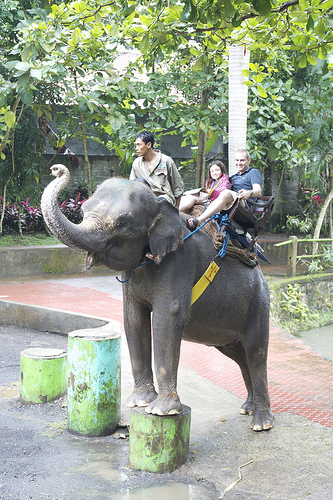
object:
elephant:
[40, 164, 278, 434]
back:
[169, 206, 275, 294]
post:
[18, 347, 65, 407]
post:
[128, 403, 191, 472]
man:
[129, 126, 183, 211]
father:
[174, 147, 264, 230]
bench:
[219, 194, 275, 252]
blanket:
[189, 202, 259, 267]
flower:
[311, 195, 322, 206]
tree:
[60, 0, 329, 176]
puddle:
[128, 484, 214, 500]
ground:
[25, 407, 333, 499]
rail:
[274, 232, 290, 254]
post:
[67, 327, 125, 437]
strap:
[186, 258, 219, 304]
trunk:
[39, 163, 88, 249]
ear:
[148, 196, 184, 267]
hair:
[134, 130, 154, 147]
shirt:
[128, 152, 184, 203]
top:
[205, 180, 235, 196]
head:
[79, 175, 159, 273]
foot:
[145, 388, 184, 417]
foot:
[251, 410, 280, 437]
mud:
[150, 485, 180, 499]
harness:
[189, 202, 258, 307]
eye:
[112, 213, 128, 230]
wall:
[4, 244, 86, 273]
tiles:
[272, 321, 330, 430]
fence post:
[285, 234, 299, 277]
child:
[205, 159, 231, 204]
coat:
[205, 174, 233, 205]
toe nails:
[168, 408, 180, 416]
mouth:
[83, 243, 102, 273]